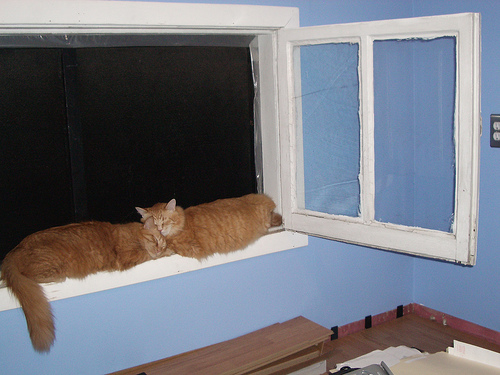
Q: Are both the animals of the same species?
A: Yes, all the animals are cats.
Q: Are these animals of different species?
A: No, all the animals are cats.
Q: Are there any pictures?
A: No, there are no pictures.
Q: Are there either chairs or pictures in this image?
A: No, there are no pictures or chairs.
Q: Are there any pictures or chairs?
A: No, there are no pictures or chairs.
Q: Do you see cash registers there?
A: No, there are no cash registers.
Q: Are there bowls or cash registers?
A: No, there are no cash registers or bowls.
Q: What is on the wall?
A: The power outlet is on the wall.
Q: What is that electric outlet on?
A: The electric outlet is on the wall.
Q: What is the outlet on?
A: The electric outlet is on the wall.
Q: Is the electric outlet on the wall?
A: Yes, the electric outlet is on the wall.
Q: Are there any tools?
A: No, there are no tools.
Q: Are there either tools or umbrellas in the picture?
A: No, there are no tools or umbrellas.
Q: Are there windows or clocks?
A: Yes, there is a window.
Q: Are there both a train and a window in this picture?
A: No, there is a window but no trains.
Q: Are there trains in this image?
A: No, there are no trains.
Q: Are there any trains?
A: No, there are no trains.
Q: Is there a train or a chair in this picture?
A: No, there are no trains or chairs.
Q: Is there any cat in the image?
A: Yes, there is a cat.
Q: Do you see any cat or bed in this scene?
A: Yes, there is a cat.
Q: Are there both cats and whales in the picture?
A: No, there is a cat but no whales.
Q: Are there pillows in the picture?
A: No, there are no pillows.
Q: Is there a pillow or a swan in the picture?
A: No, there are no pillows or swans.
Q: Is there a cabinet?
A: No, there are no cabinets.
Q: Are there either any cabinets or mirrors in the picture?
A: No, there are no cabinets or mirrors.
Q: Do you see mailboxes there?
A: No, there are no mailboxes.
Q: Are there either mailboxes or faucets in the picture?
A: No, there are no mailboxes or faucets.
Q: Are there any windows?
A: Yes, there is a window.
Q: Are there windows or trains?
A: Yes, there is a window.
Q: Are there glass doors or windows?
A: Yes, there is a glass window.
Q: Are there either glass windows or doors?
A: Yes, there is a glass window.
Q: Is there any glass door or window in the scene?
A: Yes, there is a glass window.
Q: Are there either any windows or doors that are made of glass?
A: Yes, the window is made of glass.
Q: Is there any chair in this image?
A: No, there are no chairs.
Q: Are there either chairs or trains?
A: No, there are no chairs or trains.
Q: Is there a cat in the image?
A: Yes, there is a cat.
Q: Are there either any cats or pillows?
A: Yes, there is a cat.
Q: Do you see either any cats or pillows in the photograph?
A: Yes, there is a cat.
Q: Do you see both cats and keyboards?
A: No, there is a cat but no keyboards.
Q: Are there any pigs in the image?
A: No, there are no pigs.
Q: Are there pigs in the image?
A: No, there are no pigs.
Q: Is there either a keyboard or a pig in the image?
A: No, there are no pigs or keyboards.